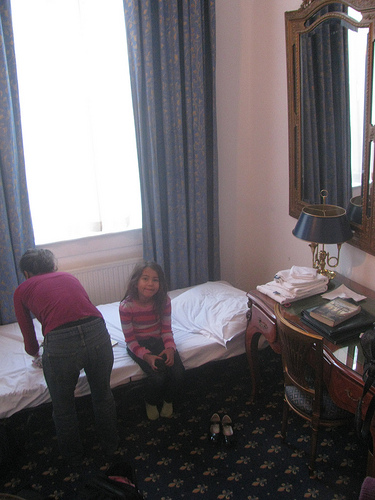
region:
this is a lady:
[18, 233, 120, 447]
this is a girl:
[124, 265, 184, 391]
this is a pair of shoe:
[207, 404, 231, 452]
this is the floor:
[173, 451, 227, 485]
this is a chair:
[280, 324, 311, 442]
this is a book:
[320, 292, 346, 322]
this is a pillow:
[187, 279, 233, 316]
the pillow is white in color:
[203, 295, 220, 316]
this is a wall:
[218, 68, 274, 228]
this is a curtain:
[137, 47, 198, 231]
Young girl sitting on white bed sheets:
[120, 260, 182, 416]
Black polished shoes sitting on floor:
[207, 409, 231, 440]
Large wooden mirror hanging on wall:
[282, 0, 372, 255]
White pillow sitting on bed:
[168, 277, 244, 344]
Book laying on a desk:
[308, 294, 356, 324]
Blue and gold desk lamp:
[291, 187, 348, 284]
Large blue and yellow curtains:
[120, 0, 213, 257]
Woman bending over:
[13, 247, 118, 461]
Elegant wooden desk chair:
[271, 303, 361, 468]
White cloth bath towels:
[259, 264, 328, 302]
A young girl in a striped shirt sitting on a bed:
[110, 260, 209, 423]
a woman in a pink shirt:
[7, 248, 125, 464]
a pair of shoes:
[203, 409, 240, 450]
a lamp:
[294, 188, 352, 289]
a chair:
[255, 301, 358, 479]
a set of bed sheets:
[250, 264, 331, 304]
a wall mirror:
[280, 0, 373, 257]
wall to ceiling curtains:
[115, 2, 241, 284]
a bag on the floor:
[74, 462, 172, 498]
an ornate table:
[238, 249, 373, 445]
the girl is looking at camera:
[120, 261, 180, 304]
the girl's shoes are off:
[142, 392, 262, 456]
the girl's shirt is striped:
[112, 285, 184, 354]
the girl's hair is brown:
[116, 254, 179, 310]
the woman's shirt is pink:
[7, 275, 111, 326]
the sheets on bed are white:
[0, 276, 298, 381]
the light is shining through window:
[18, 87, 140, 234]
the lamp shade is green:
[284, 190, 367, 280]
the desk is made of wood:
[240, 252, 371, 470]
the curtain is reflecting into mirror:
[301, 31, 355, 199]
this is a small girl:
[120, 250, 175, 394]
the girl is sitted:
[121, 265, 180, 401]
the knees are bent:
[152, 357, 186, 387]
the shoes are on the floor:
[203, 410, 236, 452]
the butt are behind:
[56, 328, 104, 369]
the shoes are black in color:
[207, 408, 238, 442]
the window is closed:
[45, 117, 128, 219]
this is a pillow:
[194, 286, 240, 326]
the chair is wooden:
[285, 333, 324, 420]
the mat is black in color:
[249, 435, 289, 498]